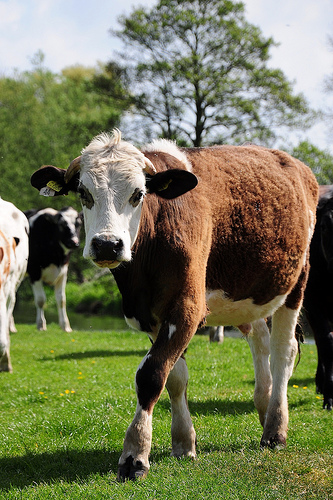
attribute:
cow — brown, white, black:
[16, 114, 331, 485]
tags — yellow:
[34, 177, 68, 203]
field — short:
[5, 307, 329, 497]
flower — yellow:
[54, 384, 79, 401]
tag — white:
[32, 185, 58, 203]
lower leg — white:
[108, 319, 309, 487]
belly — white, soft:
[206, 300, 278, 329]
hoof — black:
[107, 448, 155, 484]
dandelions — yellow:
[247, 440, 328, 495]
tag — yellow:
[43, 177, 65, 195]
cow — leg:
[23, 199, 85, 335]